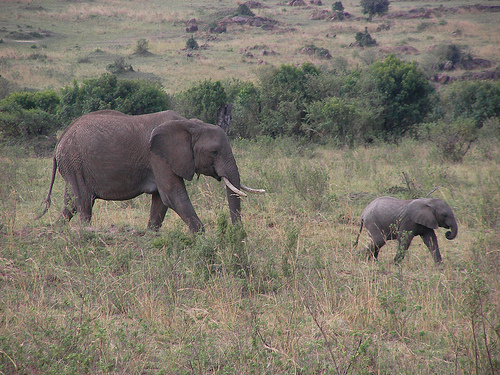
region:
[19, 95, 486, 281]
two animals walking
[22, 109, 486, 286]
two elephants in field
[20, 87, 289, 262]
a large elephant with tusks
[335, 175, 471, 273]
a baby elephant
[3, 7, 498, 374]
scene of two animals out in field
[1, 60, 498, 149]
a row of green trees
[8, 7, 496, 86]
another field in background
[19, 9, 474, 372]
a sunny day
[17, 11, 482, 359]
a scene outside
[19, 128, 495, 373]
green and brown grass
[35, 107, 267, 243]
Large gray elephant following a baby elephant.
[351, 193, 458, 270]
Baby elephant walking in front of a larger elephant.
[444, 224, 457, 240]
Small trunk of a baby elephant.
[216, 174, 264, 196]
Two tusks on the face of an elephant.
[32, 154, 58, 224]
Long thin tail of a large elephant.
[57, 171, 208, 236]
Four legs on a large gray elephant.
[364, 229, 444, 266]
Four legs on a small baby elephant.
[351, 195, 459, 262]
Tiny gray elephant.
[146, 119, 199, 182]
A large gray elephants right ear.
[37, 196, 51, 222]
Very hairy end of a large elephant.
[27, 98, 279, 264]
gray adult elephant walking through the grass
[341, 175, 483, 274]
gray baby elephant walking through the grass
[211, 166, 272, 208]
two long white tusks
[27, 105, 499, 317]
two elephants walking through the grass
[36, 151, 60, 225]
long and thin tail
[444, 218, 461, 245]
tiny gray trunk curled in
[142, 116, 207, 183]
big and floppy gray ear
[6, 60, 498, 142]
green bushes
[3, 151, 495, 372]
brown and gray tall grass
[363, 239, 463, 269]
four little gray legs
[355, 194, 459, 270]
a baby elephant in a field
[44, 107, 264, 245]
a large elephant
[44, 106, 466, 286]
a mother elephant chases after her young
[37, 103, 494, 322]
elephants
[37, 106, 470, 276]
two elephants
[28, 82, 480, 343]
two elephants in a field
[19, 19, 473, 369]
two elephants in the wild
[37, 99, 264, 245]
the large elephant has tusks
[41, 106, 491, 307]
the elephants are walking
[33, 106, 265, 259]
Large gray elephant following behind a baby elephant.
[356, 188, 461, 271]
Small baby gray elephant.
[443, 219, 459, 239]
Little curled up baby elephant trunk.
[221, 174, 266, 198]
Two white tusks on the front of a gray elephants face.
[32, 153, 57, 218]
A larger gray elephants tail.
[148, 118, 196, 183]
A large elephant with tusks right side ear.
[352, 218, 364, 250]
Thin little tail on a baby elephant.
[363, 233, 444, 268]
Four legs of a baby gray elephant.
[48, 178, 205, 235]
Four legs on a larger gray elephant.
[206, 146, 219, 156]
Right side eye of a large gray elephant.